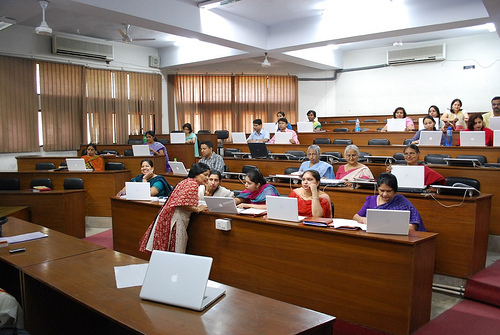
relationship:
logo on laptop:
[170, 275, 180, 288] [138, 241, 227, 310]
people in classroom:
[79, 97, 499, 251] [3, 3, 499, 333]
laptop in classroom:
[138, 241, 227, 310] [3, 3, 499, 333]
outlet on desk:
[212, 217, 233, 233] [109, 197, 440, 330]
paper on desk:
[333, 215, 361, 233] [109, 197, 440, 330]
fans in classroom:
[246, 51, 280, 73] [3, 3, 499, 333]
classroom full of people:
[3, 3, 499, 333] [79, 97, 499, 251]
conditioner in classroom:
[53, 34, 118, 65] [3, 3, 499, 333]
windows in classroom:
[3, 54, 304, 148] [3, 3, 499, 333]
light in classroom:
[31, 1, 54, 40] [3, 3, 499, 333]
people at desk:
[79, 97, 499, 251] [109, 197, 440, 330]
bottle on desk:
[446, 126, 456, 146] [109, 197, 440, 330]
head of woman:
[138, 160, 156, 176] [123, 159, 167, 198]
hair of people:
[188, 161, 209, 177] [138, 162, 211, 254]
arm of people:
[183, 198, 208, 214] [138, 162, 211, 254]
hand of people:
[198, 200, 208, 214] [138, 162, 211, 254]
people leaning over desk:
[138, 162, 211, 254] [109, 197, 440, 330]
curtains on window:
[0, 56, 300, 154] [0, 54, 298, 152]